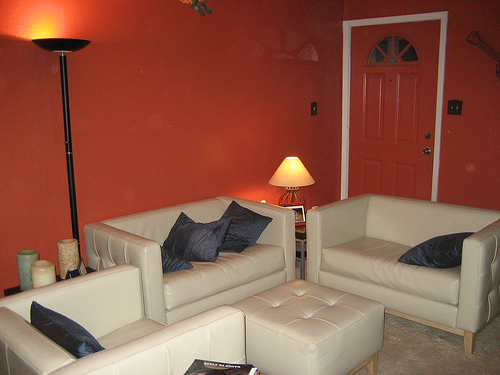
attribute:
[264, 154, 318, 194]
shade — yellow, lamp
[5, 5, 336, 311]
wall — orange, red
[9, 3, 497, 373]
room — living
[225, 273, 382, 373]
ottoman — white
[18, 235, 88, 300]
candles — set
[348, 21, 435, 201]
door — red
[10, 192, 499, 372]
furniture — white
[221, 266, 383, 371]
ottoman — white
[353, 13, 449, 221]
door — red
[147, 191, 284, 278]
pillows — blue, throw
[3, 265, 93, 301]
table — side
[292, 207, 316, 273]
table — side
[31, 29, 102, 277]
lamp — black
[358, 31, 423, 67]
insert — window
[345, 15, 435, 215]
door — red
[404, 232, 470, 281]
pillow — blue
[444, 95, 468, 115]
switch — light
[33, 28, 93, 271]
lamp — tall, black, on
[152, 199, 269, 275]
pillows — three, blue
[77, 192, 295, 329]
couch — white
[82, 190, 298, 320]
couch — with pillows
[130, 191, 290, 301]
couch — with three pillows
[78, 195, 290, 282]
couch — with three blue pillows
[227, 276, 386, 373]
white ottoman — square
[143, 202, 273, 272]
pillows — on the couch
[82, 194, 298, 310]
couch — white, leather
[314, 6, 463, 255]
door — red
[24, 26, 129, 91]
lamp — tall , black 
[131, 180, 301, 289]
pillows — blue 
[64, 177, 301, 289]
sofa — white 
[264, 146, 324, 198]
lamp — small 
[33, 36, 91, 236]
floor lamp — tall, black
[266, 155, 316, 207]
lamp — on, small